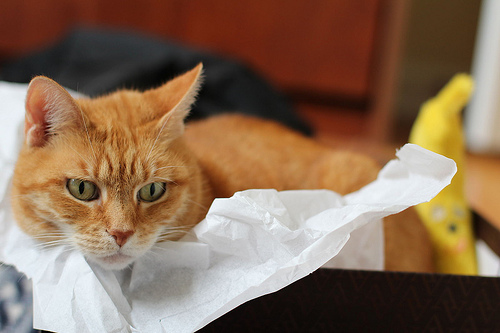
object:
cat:
[9, 61, 437, 274]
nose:
[102, 220, 138, 249]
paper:
[196, 142, 459, 299]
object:
[404, 71, 478, 181]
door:
[391, 33, 469, 99]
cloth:
[0, 23, 318, 136]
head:
[10, 60, 209, 270]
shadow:
[126, 263, 194, 302]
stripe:
[87, 126, 159, 188]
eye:
[58, 168, 108, 209]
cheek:
[57, 204, 172, 266]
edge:
[398, 143, 456, 190]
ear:
[20, 73, 84, 148]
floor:
[346, 134, 391, 148]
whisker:
[30, 221, 196, 273]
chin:
[93, 251, 135, 271]